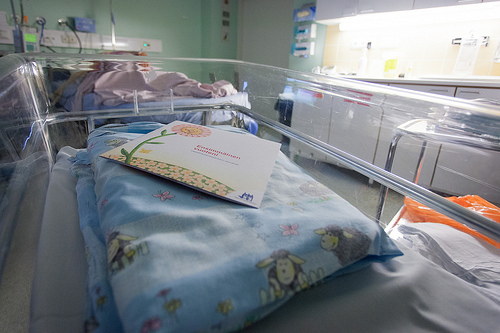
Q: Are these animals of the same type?
A: No, there are both sheep and bugs.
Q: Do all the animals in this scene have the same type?
A: No, they are sheep and bugs.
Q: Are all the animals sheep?
A: No, there are both sheep and bugs.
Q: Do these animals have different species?
A: Yes, they are sheep and bugs.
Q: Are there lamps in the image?
A: No, there are no lamps.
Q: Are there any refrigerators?
A: No, there are no refrigerators.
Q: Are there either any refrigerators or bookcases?
A: No, there are no refrigerators or bookcases.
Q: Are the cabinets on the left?
A: No, the cabinets are on the right of the image.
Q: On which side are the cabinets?
A: The cabinets are on the right of the image.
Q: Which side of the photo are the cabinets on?
A: The cabinets are on the right of the image.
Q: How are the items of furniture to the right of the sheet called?
A: The pieces of furniture are cabinets.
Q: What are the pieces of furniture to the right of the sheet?
A: The pieces of furniture are cabinets.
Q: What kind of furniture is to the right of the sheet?
A: The pieces of furniture are cabinets.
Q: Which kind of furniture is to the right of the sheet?
A: The pieces of furniture are cabinets.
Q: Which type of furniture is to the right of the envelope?
A: The pieces of furniture are cabinets.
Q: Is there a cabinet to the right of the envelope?
A: Yes, there are cabinets to the right of the envelope.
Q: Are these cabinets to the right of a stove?
A: No, the cabinets are to the right of the envelope.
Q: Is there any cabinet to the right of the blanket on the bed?
A: Yes, there are cabinets to the right of the blanket.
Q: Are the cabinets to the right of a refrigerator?
A: No, the cabinets are to the right of the blanket.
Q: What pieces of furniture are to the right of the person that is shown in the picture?
A: The pieces of furniture are cabinets.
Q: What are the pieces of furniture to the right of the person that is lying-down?
A: The pieces of furniture are cabinets.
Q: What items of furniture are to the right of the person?
A: The pieces of furniture are cabinets.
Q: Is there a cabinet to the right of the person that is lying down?
A: Yes, there are cabinets to the right of the person.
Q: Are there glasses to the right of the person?
A: No, there are cabinets to the right of the person.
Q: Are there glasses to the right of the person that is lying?
A: No, there are cabinets to the right of the person.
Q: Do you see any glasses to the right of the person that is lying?
A: No, there are cabinets to the right of the person.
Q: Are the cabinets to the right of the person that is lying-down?
A: Yes, the cabinets are to the right of the person.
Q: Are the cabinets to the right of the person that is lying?
A: Yes, the cabinets are to the right of the person.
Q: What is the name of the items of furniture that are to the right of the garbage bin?
A: The pieces of furniture are cabinets.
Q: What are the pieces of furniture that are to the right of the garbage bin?
A: The pieces of furniture are cabinets.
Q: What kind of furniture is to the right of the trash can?
A: The pieces of furniture are cabinets.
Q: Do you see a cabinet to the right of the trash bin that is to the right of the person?
A: Yes, there are cabinets to the right of the garbage bin.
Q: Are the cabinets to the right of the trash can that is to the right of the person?
A: Yes, the cabinets are to the right of the trash can.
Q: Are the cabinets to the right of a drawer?
A: No, the cabinets are to the right of the trash can.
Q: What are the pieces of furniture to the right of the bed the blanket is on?
A: The pieces of furniture are cabinets.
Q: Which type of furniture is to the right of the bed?
A: The pieces of furniture are cabinets.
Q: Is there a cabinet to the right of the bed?
A: Yes, there are cabinets to the right of the bed.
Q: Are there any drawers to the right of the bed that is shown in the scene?
A: No, there are cabinets to the right of the bed.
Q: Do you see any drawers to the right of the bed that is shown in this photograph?
A: No, there are cabinets to the right of the bed.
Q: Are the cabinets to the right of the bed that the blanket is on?
A: Yes, the cabinets are to the right of the bed.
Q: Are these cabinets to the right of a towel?
A: No, the cabinets are to the right of the bed.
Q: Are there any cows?
A: No, there are no cows.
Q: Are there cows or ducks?
A: No, there are no cows or ducks.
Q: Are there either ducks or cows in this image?
A: No, there are no cows or ducks.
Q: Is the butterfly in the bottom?
A: Yes, the butterfly is in the bottom of the image.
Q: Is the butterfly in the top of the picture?
A: No, the butterfly is in the bottom of the image.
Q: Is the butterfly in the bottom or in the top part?
A: The butterfly is in the bottom of the image.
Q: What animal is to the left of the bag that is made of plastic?
A: The animal is a butterfly.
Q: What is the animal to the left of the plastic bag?
A: The animal is a butterfly.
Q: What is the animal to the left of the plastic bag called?
A: The animal is a butterfly.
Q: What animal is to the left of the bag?
A: The animal is a butterfly.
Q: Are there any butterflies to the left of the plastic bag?
A: Yes, there is a butterfly to the left of the bag.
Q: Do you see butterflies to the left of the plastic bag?
A: Yes, there is a butterfly to the left of the bag.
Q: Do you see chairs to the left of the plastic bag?
A: No, there is a butterfly to the left of the bag.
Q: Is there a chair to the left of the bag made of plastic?
A: No, there is a butterfly to the left of the bag.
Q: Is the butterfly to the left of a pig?
A: No, the butterfly is to the left of the sheep.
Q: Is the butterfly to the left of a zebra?
A: No, the butterfly is to the left of a sheep.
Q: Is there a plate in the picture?
A: No, there are no plates.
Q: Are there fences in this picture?
A: No, there are no fences.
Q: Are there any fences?
A: No, there are no fences.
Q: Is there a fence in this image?
A: No, there are no fences.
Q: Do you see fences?
A: No, there are no fences.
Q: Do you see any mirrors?
A: No, there are no mirrors.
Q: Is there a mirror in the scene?
A: No, there are no mirrors.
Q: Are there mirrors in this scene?
A: No, there are no mirrors.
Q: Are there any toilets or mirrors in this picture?
A: No, there are no mirrors or toilets.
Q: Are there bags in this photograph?
A: Yes, there is a bag.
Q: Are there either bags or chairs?
A: Yes, there is a bag.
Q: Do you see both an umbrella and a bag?
A: No, there is a bag but no umbrellas.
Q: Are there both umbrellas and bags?
A: No, there is a bag but no umbrellas.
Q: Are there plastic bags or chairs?
A: Yes, there is a plastic bag.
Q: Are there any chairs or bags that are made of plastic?
A: Yes, the bag is made of plastic.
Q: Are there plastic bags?
A: Yes, there is a bag that is made of plastic.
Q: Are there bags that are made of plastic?
A: Yes, there is a bag that is made of plastic.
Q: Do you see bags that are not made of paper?
A: Yes, there is a bag that is made of plastic.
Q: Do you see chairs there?
A: No, there are no chairs.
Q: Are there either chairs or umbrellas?
A: No, there are no chairs or umbrellas.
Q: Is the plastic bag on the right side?
A: Yes, the bag is on the right of the image.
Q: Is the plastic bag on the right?
A: Yes, the bag is on the right of the image.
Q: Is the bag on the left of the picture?
A: No, the bag is on the right of the image.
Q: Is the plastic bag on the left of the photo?
A: No, the bag is on the right of the image.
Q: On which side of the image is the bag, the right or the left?
A: The bag is on the right of the image.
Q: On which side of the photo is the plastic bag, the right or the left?
A: The bag is on the right of the image.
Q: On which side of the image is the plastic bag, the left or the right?
A: The bag is on the right of the image.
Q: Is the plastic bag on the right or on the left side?
A: The bag is on the right of the image.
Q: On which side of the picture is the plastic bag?
A: The bag is on the right of the image.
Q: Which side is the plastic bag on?
A: The bag is on the right of the image.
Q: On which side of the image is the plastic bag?
A: The bag is on the right of the image.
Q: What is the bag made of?
A: The bag is made of plastic.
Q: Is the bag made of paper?
A: No, the bag is made of plastic.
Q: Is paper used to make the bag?
A: No, the bag is made of plastic.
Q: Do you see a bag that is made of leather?
A: No, there is a bag but it is made of plastic.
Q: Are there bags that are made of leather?
A: No, there is a bag but it is made of plastic.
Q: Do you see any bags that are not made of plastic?
A: No, there is a bag but it is made of plastic.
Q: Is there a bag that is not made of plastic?
A: No, there is a bag but it is made of plastic.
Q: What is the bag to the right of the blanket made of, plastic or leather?
A: The bag is made of plastic.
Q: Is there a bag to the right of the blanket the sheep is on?
A: Yes, there is a bag to the right of the blanket.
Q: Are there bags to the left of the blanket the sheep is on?
A: No, the bag is to the right of the blanket.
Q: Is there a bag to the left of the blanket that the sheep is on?
A: No, the bag is to the right of the blanket.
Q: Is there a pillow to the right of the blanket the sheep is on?
A: No, there is a bag to the right of the blanket.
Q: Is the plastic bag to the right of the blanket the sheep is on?
A: Yes, the bag is to the right of the blanket.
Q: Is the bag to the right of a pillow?
A: No, the bag is to the right of the blanket.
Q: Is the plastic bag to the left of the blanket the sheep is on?
A: No, the bag is to the right of the blanket.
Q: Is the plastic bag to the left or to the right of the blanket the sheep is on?
A: The bag is to the right of the blanket.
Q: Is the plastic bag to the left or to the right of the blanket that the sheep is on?
A: The bag is to the right of the blanket.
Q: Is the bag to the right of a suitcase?
A: No, the bag is to the right of the sheep.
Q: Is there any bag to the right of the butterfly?
A: Yes, there is a bag to the right of the butterfly.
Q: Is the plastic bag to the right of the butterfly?
A: Yes, the bag is to the right of the butterfly.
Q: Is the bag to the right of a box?
A: No, the bag is to the right of the butterfly.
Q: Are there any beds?
A: Yes, there is a bed.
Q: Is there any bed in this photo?
A: Yes, there is a bed.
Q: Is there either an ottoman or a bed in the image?
A: Yes, there is a bed.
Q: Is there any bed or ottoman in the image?
A: Yes, there is a bed.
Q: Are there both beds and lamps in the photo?
A: No, there is a bed but no lamps.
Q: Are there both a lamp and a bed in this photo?
A: No, there is a bed but no lamps.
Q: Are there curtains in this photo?
A: No, there are no curtains.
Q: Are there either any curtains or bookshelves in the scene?
A: No, there are no curtains or bookshelves.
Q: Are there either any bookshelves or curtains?
A: No, there are no curtains or bookshelves.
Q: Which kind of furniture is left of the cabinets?
A: The piece of furniture is a bed.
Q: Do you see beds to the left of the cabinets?
A: Yes, there is a bed to the left of the cabinets.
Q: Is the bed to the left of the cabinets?
A: Yes, the bed is to the left of the cabinets.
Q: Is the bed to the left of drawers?
A: No, the bed is to the left of the cabinets.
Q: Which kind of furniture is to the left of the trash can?
A: The piece of furniture is a bed.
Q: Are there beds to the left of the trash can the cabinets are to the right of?
A: Yes, there is a bed to the left of the trash can.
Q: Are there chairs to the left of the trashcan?
A: No, there is a bed to the left of the trashcan.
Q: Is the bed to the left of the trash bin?
A: Yes, the bed is to the left of the trash bin.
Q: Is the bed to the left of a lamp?
A: No, the bed is to the left of the trash bin.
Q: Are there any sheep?
A: Yes, there is a sheep.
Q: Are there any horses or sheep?
A: Yes, there is a sheep.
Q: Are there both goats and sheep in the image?
A: No, there is a sheep but no goats.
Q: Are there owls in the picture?
A: No, there are no owls.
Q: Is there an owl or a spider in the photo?
A: No, there are no owls or spiders.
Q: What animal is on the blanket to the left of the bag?
A: The sheep is on the blanket.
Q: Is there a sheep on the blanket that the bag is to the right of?
A: Yes, there is a sheep on the blanket.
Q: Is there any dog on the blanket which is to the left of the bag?
A: No, there is a sheep on the blanket.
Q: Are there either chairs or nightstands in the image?
A: No, there are no chairs or nightstands.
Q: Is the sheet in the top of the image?
A: Yes, the sheet is in the top of the image.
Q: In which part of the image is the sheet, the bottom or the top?
A: The sheet is in the top of the image.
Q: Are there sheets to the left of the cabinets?
A: Yes, there is a sheet to the left of the cabinets.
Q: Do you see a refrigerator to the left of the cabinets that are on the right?
A: No, there is a sheet to the left of the cabinets.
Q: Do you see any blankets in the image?
A: Yes, there is a blanket.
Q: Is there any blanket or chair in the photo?
A: Yes, there is a blanket.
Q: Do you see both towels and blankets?
A: No, there is a blanket but no towels.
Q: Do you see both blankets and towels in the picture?
A: No, there is a blanket but no towels.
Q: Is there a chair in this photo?
A: No, there are no chairs.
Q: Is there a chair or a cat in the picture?
A: No, there are no chairs or cats.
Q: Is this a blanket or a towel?
A: This is a blanket.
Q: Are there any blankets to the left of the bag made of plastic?
A: Yes, there is a blanket to the left of the bag.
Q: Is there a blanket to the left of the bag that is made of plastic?
A: Yes, there is a blanket to the left of the bag.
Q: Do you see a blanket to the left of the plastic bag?
A: Yes, there is a blanket to the left of the bag.